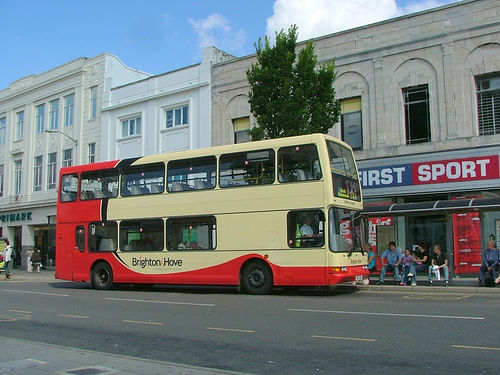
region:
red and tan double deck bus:
[54, 139, 345, 299]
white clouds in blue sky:
[282, 3, 312, 31]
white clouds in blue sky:
[121, 15, 208, 65]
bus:
[37, 135, 371, 299]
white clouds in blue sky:
[24, 19, 74, 60]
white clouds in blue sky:
[118, 12, 183, 46]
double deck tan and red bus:
[39, 141, 368, 286]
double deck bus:
[44, 127, 370, 302]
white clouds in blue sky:
[119, 23, 167, 45]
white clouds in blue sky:
[200, 4, 234, 25]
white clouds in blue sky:
[282, 5, 332, 24]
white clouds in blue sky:
[17, 7, 82, 42]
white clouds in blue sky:
[118, 8, 180, 40]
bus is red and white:
[54, 132, 368, 292]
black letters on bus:
[129, 252, 188, 272]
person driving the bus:
[287, 216, 319, 246]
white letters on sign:
[414, 158, 497, 186]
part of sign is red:
[409, 147, 499, 192]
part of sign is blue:
[357, 162, 410, 189]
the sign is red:
[452, 210, 483, 275]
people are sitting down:
[366, 231, 496, 281]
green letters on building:
[2, 207, 37, 227]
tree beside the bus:
[243, 22, 342, 137]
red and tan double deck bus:
[50, 132, 377, 300]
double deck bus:
[47, 136, 357, 300]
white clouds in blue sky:
[12, 8, 72, 56]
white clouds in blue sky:
[72, 6, 113, 37]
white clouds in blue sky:
[134, 9, 192, 56]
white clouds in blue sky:
[120, 12, 208, 47]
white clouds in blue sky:
[18, 16, 132, 57]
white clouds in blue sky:
[140, 6, 205, 40]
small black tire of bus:
[218, 243, 274, 320]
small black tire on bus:
[78, 251, 123, 296]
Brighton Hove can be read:
[120, 240, 191, 276]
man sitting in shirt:
[373, 235, 408, 292]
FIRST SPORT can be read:
[358, 152, 488, 196]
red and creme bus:
[43, 145, 349, 332]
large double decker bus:
[30, 132, 376, 313]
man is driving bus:
[284, 194, 319, 259]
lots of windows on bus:
[58, 167, 191, 251]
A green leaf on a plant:
[268, 94, 270, 96]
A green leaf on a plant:
[288, 99, 291, 103]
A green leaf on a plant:
[303, 97, 305, 99]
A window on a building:
[183, 105, 189, 125]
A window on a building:
[176, 105, 181, 125]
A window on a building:
[166, 108, 173, 125]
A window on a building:
[136, 116, 141, 133]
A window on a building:
[129, 118, 134, 134]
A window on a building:
[120, 120, 128, 137]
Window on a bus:
[283, 209, 323, 251]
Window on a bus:
[165, 216, 217, 251]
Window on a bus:
[118, 219, 163, 250]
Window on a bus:
[88, 220, 115, 253]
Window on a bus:
[59, 174, 79, 201]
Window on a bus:
[80, 169, 116, 196]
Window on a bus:
[120, 160, 162, 196]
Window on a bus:
[168, 155, 213, 191]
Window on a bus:
[221, 148, 271, 188]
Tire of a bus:
[239, 257, 274, 297]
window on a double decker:
[217, 149, 279, 187]